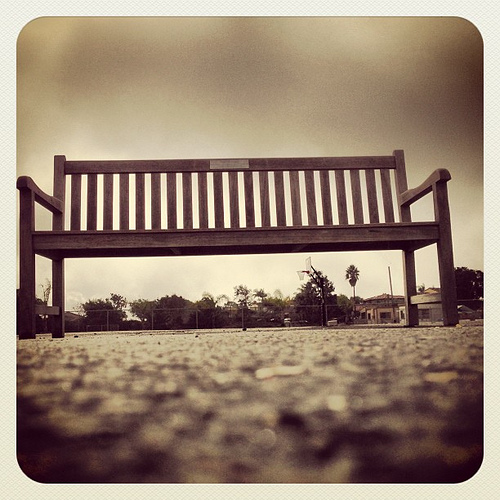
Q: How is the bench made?
A: Of wood.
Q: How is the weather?
A: Overcast.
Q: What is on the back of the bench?
A: A plaque.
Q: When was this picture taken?
A: Early evening.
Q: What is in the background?
A: Trees.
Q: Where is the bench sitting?
A: A park.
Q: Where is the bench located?
A: In a park.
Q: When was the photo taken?
A: During daylight hours.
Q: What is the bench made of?
A: Wood.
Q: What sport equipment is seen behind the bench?
A: Basketball hoop.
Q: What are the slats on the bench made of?
A: Wood.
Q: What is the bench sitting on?
A: Gravel.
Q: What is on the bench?
A: An engraved plaque.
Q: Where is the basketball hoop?
A: Behind the bench.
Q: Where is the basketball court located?
A: In a park.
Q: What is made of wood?
A: Bench.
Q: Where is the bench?
A: On grass.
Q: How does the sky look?
A: Overcast.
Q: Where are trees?
A: In the distance.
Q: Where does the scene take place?
A: On a grassy park.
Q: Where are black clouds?
A: In the sky.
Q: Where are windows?
A: On the buildings.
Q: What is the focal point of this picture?
A: The bench.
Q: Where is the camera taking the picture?
A: On the ground.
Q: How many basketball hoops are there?
A: One.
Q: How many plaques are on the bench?
A: One.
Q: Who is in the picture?
A: Noone.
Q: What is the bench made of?
A: Wood.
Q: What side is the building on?
A: Right.